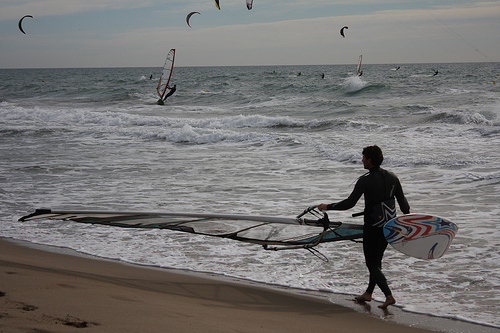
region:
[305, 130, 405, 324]
person walking on the beach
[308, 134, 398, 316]
person wearing a wet suit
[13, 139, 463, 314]
person carrying a windsurfing board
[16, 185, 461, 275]
windsurfing board with red white and blue design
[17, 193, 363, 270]
big sail with a handle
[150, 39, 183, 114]
person windsurfing in the ocean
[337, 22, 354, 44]
bird in the sky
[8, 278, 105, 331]
footprints on the beach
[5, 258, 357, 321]
shadow of the sail on the beach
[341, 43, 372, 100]
person riding a wave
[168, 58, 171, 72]
A surfing sail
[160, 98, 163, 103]
A surfing boat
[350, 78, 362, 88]
A large wave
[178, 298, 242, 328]
Sand without foot marks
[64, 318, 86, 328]
A foot mark in the sand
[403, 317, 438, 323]
Water on the sand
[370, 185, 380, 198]
A blackish wet suit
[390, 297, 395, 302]
Heel raised away from the sand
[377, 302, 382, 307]
Foot toes in the sand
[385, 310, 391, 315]
Foot casting shadow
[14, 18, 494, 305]
Image taken at the beach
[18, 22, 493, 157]
Many people in the ocean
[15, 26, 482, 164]
Most of the people are kitesurfing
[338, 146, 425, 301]
Man wearing a wetsuit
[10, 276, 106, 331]
Footprints in the sand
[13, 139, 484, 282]
Man carrying his kitesurfing equipment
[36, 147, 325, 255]
Shallow water near shore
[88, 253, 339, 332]
Shadow on the ground from the kite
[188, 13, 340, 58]
Strings connected to kites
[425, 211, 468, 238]
Star on the board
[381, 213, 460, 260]
a red, white, and blue surf board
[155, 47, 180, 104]
a person on the ocean surfboard sailing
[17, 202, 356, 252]
a big surf board sail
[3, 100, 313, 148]
white small waves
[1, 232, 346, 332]
part of a sandy beach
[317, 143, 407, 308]
a man in a black wet suite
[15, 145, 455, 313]
a man carrying a surf board and sail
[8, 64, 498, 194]
part of a very choppy ocean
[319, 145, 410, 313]
a man walking on a beach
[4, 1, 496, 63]
a piece of sky with clouds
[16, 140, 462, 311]
surfer carrying board attached to sail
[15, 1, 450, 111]
watersports in the ocean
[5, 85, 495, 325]
edge of water covered in white surf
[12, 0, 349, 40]
curved arcs of kites in blue and white sky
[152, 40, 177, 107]
surfer leaning to side of board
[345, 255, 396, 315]
feet on edge of water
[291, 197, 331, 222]
hand on metal banding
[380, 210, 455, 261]
smile, star and stripes on board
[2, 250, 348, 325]
shadow of sail on sand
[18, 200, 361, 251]
curved panels along pole